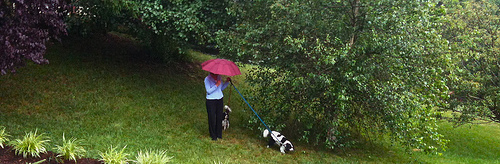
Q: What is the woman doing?
A: Walking her dog.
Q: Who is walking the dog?
A: The woman.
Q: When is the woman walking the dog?
A: Now.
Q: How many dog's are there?
A: One.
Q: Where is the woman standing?
A: Next to the tree.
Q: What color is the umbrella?
A: Red.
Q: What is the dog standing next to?
A: A tree.